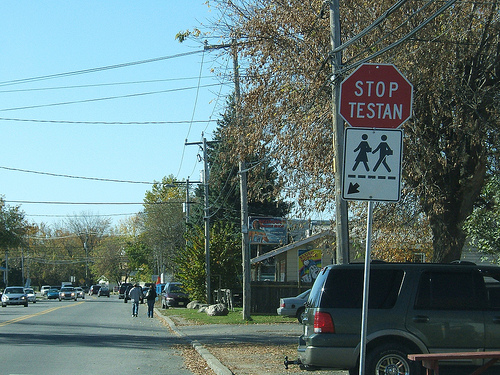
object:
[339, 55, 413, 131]
sign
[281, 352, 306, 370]
hitch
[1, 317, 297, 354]
shadow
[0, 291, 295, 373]
ground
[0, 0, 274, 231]
sky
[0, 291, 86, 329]
lines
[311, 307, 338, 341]
tail light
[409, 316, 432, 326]
door handle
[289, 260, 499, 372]
suv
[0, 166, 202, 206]
lines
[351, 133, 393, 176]
pedestrians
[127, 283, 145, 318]
pedestrians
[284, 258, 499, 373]
car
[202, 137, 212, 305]
pole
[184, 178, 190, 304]
pole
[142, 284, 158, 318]
people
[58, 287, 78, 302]
car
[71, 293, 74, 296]
headlight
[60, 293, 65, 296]
headlight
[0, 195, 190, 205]
power line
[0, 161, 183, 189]
power line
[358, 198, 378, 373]
pole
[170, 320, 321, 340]
driveway